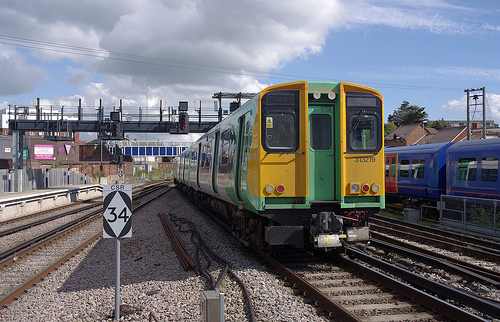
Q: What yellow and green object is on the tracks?
A: There is a train on the tracks.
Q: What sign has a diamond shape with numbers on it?
A: There is a sign with the number 34 next to the train.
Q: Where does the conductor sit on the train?
A: The conductor sits in the first rail car.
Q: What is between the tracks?
A: Ballast.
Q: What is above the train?
A: The sky.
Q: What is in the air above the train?
A: Power lines.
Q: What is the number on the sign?
A: 34.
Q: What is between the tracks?
A: Wooden ties.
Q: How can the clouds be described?
A: White and puffy.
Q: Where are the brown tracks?
A: Left of the numbered sign.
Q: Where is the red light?
A: On the bridge.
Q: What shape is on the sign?
A: Diamond.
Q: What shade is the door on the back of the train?
A: Green.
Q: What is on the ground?
A: Rubber hoses.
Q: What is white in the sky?
A: Clouds.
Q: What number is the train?
A: 313219.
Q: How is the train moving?
A: Train tracks.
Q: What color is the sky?
A: Blue.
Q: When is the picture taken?
A: Daytime.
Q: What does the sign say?
A: CBR 34.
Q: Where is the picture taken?
A: Train tracks.